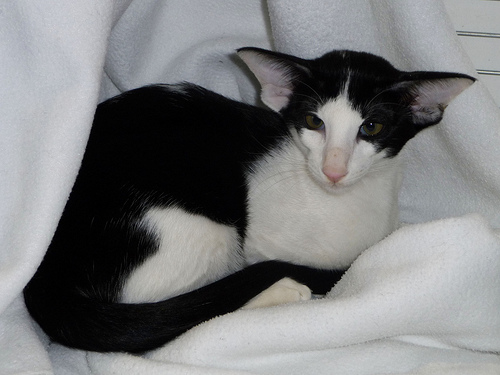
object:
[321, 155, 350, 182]
nose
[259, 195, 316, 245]
fur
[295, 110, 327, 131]
eyes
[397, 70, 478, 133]
ears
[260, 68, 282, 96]
insides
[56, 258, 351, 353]
tail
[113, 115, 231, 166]
fur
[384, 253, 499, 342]
towel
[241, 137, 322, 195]
whiskers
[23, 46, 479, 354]
cat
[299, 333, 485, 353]
wrinkle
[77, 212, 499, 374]
blanket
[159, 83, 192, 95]
spot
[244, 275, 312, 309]
foot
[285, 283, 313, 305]
toe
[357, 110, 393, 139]
eye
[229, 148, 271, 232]
black & white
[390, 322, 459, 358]
white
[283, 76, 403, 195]
face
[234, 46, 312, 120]
ear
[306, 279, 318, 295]
nail